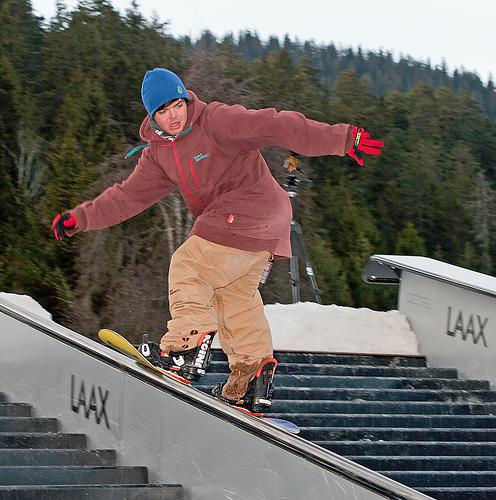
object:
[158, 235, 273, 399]
pants are brown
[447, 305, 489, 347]
text reads laax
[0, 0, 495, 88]
sky is clear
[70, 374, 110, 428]
ax written on wall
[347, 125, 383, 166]
gloves are orange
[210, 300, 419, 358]
snow on top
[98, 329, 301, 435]
snowboard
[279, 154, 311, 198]
camera on a tripod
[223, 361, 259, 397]
wet spot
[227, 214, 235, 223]
red tag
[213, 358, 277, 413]
snowboarding boot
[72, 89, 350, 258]
brown coat on boy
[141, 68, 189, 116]
blue wool cap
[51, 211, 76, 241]
red glove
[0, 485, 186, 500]
gray outdoor steps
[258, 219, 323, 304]
tripod behind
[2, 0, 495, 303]
green forest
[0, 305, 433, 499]
ledge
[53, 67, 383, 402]
boy